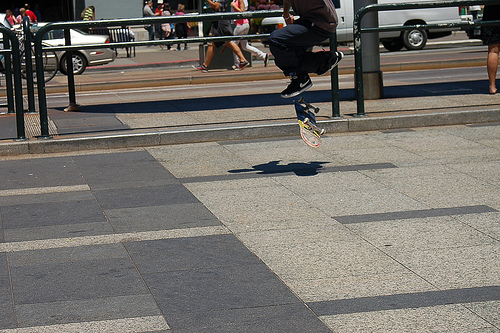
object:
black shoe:
[280, 72, 313, 98]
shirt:
[82, 5, 94, 21]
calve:
[486, 49, 498, 65]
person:
[226, 0, 269, 70]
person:
[191, 1, 249, 73]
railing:
[0, 0, 500, 136]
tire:
[57, 50, 87, 75]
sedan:
[3, 19, 120, 77]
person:
[20, 2, 39, 24]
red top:
[25, 9, 38, 23]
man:
[268, 1, 344, 98]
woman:
[174, 2, 191, 50]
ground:
[6, 19, 496, 331]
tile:
[93, 183, 201, 210]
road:
[0, 36, 499, 332]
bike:
[0, 23, 58, 83]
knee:
[268, 28, 300, 60]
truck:
[259, 0, 465, 52]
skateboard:
[292, 96, 327, 149]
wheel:
[303, 117, 309, 125]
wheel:
[319, 127, 326, 135]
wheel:
[292, 94, 303, 103]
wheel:
[314, 106, 320, 113]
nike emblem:
[300, 79, 309, 87]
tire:
[9, 38, 62, 84]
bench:
[87, 26, 136, 58]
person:
[118, 25, 135, 58]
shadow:
[226, 159, 333, 176]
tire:
[400, 28, 428, 50]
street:
[8, 24, 496, 90]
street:
[0, 26, 84, 95]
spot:
[382, 240, 392, 249]